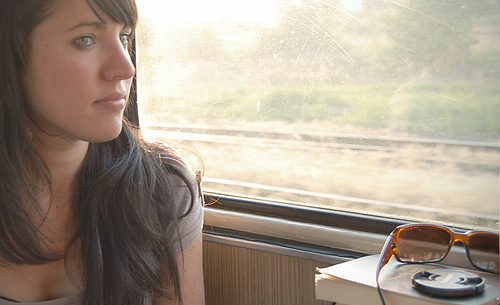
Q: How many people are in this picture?
A: 1.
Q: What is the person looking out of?
A: Window.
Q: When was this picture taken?
A: Daytime.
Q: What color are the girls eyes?
A: Green.